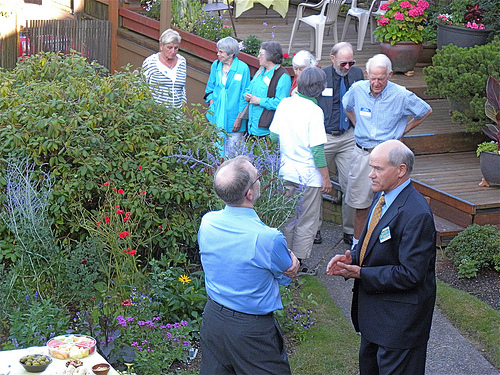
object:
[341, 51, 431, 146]
man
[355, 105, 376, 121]
name tag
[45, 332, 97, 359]
container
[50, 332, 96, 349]
fruit assortment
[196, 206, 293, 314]
shirt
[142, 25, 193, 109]
senior citizen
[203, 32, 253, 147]
senior citizen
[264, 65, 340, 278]
senior citizen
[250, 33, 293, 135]
senior citizen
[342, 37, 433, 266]
senior citizen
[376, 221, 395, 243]
badge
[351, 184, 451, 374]
suit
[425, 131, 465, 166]
ground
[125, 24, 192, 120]
people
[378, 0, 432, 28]
flowers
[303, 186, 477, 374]
suit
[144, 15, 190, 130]
woman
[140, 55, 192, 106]
shirt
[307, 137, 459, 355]
man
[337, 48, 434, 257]
man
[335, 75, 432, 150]
shirt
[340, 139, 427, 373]
man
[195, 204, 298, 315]
shirt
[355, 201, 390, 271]
tie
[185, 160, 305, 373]
man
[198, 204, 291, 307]
shirt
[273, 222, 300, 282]
arm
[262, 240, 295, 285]
arm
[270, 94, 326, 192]
shirt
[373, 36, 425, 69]
planter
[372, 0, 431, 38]
flowers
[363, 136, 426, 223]
man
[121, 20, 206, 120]
woman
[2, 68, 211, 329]
shrubs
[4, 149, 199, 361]
flowers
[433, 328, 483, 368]
path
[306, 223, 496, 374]
pathway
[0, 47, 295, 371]
garden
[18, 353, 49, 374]
bowl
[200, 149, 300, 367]
people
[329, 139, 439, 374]
man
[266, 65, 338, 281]
woman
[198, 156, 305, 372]
man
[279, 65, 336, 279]
person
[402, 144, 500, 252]
decking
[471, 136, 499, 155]
plants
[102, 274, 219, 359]
flowers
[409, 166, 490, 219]
deck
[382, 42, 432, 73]
pot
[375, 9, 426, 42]
plant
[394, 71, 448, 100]
deck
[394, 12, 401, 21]
flower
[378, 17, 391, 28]
flower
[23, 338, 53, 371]
olives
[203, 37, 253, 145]
older woman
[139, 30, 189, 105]
older woman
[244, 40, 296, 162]
older woman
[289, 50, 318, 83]
older woman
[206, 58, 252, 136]
turquoise jacket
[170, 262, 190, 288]
flower